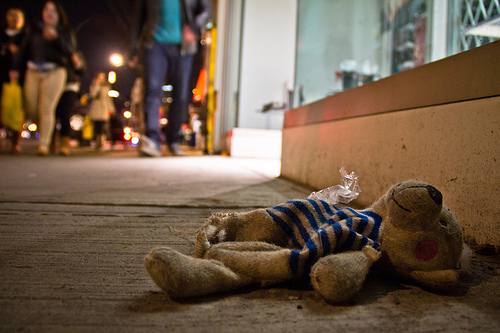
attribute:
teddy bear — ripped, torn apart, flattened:
[144, 166, 464, 304]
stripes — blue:
[269, 195, 382, 271]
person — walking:
[131, 1, 218, 155]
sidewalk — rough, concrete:
[0, 150, 499, 331]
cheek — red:
[412, 227, 442, 263]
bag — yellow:
[66, 46, 81, 72]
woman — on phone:
[83, 66, 117, 146]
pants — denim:
[138, 40, 195, 140]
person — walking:
[0, 6, 29, 150]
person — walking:
[19, 1, 71, 153]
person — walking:
[83, 65, 114, 152]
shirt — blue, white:
[265, 196, 383, 269]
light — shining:
[107, 49, 127, 69]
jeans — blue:
[139, 36, 192, 138]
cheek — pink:
[409, 230, 439, 260]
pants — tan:
[22, 69, 66, 149]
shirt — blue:
[152, 3, 184, 42]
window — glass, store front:
[289, 3, 498, 108]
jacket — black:
[126, 2, 208, 53]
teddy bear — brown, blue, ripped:
[146, 180, 474, 303]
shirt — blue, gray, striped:
[265, 197, 387, 282]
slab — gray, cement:
[2, 197, 497, 327]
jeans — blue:
[142, 42, 193, 146]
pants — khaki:
[25, 61, 68, 142]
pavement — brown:
[5, 140, 494, 330]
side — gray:
[223, 0, 303, 133]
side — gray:
[219, 1, 295, 130]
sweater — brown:
[12, 21, 77, 69]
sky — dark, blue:
[13, 4, 162, 87]